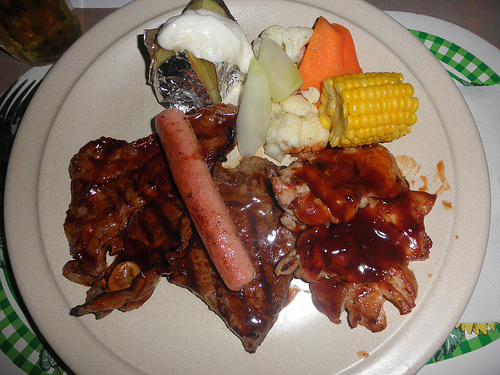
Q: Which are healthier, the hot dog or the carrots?
A: The carrots are healthier than the hot dog.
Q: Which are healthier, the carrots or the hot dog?
A: The carrots are healthier than the hot dog.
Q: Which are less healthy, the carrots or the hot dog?
A: The hot dog are less healthy than the carrots.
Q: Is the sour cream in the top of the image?
A: Yes, the sour cream is in the top of the image.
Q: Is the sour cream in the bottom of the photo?
A: No, the sour cream is in the top of the image.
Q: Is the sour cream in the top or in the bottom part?
A: The sour cream is in the top of the image.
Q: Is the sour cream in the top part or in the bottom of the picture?
A: The sour cream is in the top of the image.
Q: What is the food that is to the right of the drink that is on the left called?
A: The food is sour cream.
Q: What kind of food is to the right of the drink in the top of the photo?
A: The food is sour cream.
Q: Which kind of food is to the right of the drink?
A: The food is sour cream.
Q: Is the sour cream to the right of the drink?
A: Yes, the sour cream is to the right of the drink.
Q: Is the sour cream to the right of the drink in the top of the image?
A: Yes, the sour cream is to the right of the drink.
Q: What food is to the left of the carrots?
A: The food is sour cream.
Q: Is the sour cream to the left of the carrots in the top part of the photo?
A: Yes, the sour cream is to the left of the carrots.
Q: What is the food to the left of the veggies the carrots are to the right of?
A: The food is sour cream.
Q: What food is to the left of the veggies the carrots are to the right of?
A: The food is sour cream.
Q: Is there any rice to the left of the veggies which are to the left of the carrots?
A: No, there is sour cream to the left of the vegetables.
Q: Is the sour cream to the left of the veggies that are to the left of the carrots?
A: Yes, the sour cream is to the left of the vegetables.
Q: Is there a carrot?
A: Yes, there are carrots.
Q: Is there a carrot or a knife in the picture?
A: Yes, there are carrots.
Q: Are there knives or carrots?
A: Yes, there are carrots.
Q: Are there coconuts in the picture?
A: No, there are no coconuts.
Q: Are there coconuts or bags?
A: No, there are no coconuts or bags.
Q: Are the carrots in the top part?
A: Yes, the carrots are in the top of the image.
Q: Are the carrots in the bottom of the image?
A: No, the carrots are in the top of the image.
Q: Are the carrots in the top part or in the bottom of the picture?
A: The carrots are in the top of the image.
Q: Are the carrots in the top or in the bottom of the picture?
A: The carrots are in the top of the image.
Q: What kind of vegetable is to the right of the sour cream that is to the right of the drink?
A: The vegetables are carrots.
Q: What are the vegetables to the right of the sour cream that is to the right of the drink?
A: The vegetables are carrots.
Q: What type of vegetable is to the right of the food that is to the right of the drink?
A: The vegetables are carrots.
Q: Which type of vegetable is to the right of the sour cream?
A: The vegetables are carrots.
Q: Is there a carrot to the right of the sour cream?
A: Yes, there are carrots to the right of the sour cream.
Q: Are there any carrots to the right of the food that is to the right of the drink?
A: Yes, there are carrots to the right of the sour cream.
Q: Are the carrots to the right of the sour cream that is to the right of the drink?
A: Yes, the carrots are to the right of the sour cream.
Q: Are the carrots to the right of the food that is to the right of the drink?
A: Yes, the carrots are to the right of the sour cream.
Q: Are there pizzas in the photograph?
A: No, there are no pizzas.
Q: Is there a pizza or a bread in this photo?
A: No, there are no pizzas or breads.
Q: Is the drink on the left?
A: Yes, the drink is on the left of the image.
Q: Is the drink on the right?
A: No, the drink is on the left of the image.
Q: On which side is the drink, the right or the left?
A: The drink is on the left of the image.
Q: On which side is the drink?
A: The drink is on the left of the image.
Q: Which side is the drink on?
A: The drink is on the left of the image.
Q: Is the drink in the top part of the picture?
A: Yes, the drink is in the top of the image.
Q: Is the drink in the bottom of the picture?
A: No, the drink is in the top of the image.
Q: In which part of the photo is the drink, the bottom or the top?
A: The drink is in the top of the image.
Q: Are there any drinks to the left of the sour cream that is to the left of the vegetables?
A: Yes, there is a drink to the left of the sour cream.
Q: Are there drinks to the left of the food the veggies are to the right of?
A: Yes, there is a drink to the left of the sour cream.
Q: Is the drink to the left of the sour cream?
A: Yes, the drink is to the left of the sour cream.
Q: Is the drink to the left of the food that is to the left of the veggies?
A: Yes, the drink is to the left of the sour cream.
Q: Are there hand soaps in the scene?
A: No, there are no hand soaps.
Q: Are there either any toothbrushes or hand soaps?
A: No, there are no hand soaps or toothbrushes.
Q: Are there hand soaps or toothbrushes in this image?
A: No, there are no hand soaps or toothbrushes.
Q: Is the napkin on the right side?
A: Yes, the napkin is on the right of the image.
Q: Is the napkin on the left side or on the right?
A: The napkin is on the right of the image.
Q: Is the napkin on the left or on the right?
A: The napkin is on the right of the image.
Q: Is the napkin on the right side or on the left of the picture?
A: The napkin is on the right of the image.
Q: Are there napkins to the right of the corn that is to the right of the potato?
A: Yes, there is a napkin to the right of the corn.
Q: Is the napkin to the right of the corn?
A: Yes, the napkin is to the right of the corn.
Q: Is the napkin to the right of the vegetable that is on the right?
A: Yes, the napkin is to the right of the corn.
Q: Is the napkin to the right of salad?
A: No, the napkin is to the right of the corn.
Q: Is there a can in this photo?
A: No, there are no cans.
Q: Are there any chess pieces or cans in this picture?
A: No, there are no cans or chess pieces.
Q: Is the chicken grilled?
A: Yes, the chicken is grilled.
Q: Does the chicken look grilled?
A: Yes, the chicken is grilled.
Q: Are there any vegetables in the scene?
A: Yes, there are vegetables.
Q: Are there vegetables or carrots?
A: Yes, there are vegetables.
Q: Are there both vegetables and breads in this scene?
A: No, there are vegetables but no breads.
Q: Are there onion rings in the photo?
A: No, there are no onion rings.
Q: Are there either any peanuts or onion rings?
A: No, there are no onion rings or peanuts.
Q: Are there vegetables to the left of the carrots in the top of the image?
A: Yes, there are vegetables to the left of the carrots.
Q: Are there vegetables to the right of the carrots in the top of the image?
A: No, the vegetables are to the left of the carrots.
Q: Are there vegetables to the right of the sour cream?
A: Yes, there are vegetables to the right of the sour cream.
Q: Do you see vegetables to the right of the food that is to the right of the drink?
A: Yes, there are vegetables to the right of the sour cream.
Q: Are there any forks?
A: Yes, there is a fork.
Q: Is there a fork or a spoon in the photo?
A: Yes, there is a fork.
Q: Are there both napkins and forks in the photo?
A: Yes, there are both a fork and a napkin.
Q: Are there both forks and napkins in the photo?
A: Yes, there are both a fork and a napkin.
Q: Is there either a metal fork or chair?
A: Yes, there is a metal fork.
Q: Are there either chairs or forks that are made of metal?
A: Yes, the fork is made of metal.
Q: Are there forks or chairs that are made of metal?
A: Yes, the fork is made of metal.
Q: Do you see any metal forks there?
A: Yes, there is a metal fork.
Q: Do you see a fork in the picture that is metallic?
A: Yes, there is a fork that is metallic.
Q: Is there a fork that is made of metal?
A: Yes, there is a fork that is made of metal.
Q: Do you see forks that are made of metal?
A: Yes, there is a fork that is made of metal.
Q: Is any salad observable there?
A: No, there is no salad.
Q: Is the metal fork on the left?
A: Yes, the fork is on the left of the image.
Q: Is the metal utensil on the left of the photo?
A: Yes, the fork is on the left of the image.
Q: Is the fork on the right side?
A: No, the fork is on the left of the image.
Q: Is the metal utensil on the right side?
A: No, the fork is on the left of the image.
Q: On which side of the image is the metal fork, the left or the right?
A: The fork is on the left of the image.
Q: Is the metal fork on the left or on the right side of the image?
A: The fork is on the left of the image.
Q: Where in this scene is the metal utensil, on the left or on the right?
A: The fork is on the left of the image.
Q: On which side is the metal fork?
A: The fork is on the left of the image.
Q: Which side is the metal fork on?
A: The fork is on the left of the image.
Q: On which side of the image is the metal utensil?
A: The fork is on the left of the image.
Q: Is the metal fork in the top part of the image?
A: Yes, the fork is in the top of the image.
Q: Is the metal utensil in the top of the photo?
A: Yes, the fork is in the top of the image.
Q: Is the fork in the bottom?
A: No, the fork is in the top of the image.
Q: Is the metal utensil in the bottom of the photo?
A: No, the fork is in the top of the image.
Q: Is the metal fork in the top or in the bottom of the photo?
A: The fork is in the top of the image.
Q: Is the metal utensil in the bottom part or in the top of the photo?
A: The fork is in the top of the image.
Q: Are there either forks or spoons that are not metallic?
A: No, there is a fork but it is metallic.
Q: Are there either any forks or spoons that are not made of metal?
A: No, there is a fork but it is made of metal.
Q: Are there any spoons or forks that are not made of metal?
A: No, there is a fork but it is made of metal.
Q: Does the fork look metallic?
A: Yes, the fork is metallic.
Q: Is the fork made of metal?
A: Yes, the fork is made of metal.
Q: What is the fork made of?
A: The fork is made of metal.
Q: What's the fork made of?
A: The fork is made of metal.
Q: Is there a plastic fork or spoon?
A: No, there is a fork but it is metallic.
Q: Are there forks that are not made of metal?
A: No, there is a fork but it is made of metal.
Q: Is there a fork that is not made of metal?
A: No, there is a fork but it is made of metal.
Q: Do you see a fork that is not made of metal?
A: No, there is a fork but it is made of metal.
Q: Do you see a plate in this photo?
A: Yes, there is a plate.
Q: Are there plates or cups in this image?
A: Yes, there is a plate.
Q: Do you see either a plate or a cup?
A: Yes, there is a plate.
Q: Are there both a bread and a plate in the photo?
A: No, there is a plate but no breads.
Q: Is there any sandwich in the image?
A: No, there are no sandwiches.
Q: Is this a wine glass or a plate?
A: This is a plate.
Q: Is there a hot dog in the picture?
A: Yes, there is a hot dog.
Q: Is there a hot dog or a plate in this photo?
A: Yes, there is a hot dog.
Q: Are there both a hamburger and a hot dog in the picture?
A: No, there is a hot dog but no hamburgers.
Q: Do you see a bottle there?
A: No, there are no bottles.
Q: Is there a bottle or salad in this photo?
A: No, there are no bottles or salad.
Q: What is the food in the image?
A: The food is a hot dog.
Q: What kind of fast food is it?
A: The food is a hot dog.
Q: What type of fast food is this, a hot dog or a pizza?
A: That is a hot dog.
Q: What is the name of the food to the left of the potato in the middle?
A: The food is a hot dog.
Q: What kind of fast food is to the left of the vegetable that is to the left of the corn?
A: The food is a hot dog.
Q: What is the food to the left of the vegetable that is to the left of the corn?
A: The food is a hot dog.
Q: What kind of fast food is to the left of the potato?
A: The food is a hot dog.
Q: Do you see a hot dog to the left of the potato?
A: Yes, there is a hot dog to the left of the potato.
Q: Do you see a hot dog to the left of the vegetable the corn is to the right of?
A: Yes, there is a hot dog to the left of the potato.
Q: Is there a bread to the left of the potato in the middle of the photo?
A: No, there is a hot dog to the left of the potato.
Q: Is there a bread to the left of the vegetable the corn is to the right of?
A: No, there is a hot dog to the left of the potato.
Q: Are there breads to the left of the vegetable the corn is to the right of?
A: No, there is a hot dog to the left of the potato.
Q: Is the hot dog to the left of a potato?
A: Yes, the hot dog is to the left of a potato.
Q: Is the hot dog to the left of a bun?
A: No, the hot dog is to the left of a potato.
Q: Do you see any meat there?
A: Yes, there is meat.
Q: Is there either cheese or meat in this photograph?
A: Yes, there is meat.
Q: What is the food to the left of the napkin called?
A: The food is meat.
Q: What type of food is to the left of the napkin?
A: The food is meat.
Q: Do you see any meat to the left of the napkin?
A: Yes, there is meat to the left of the napkin.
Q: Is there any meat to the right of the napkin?
A: No, the meat is to the left of the napkin.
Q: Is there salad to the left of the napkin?
A: No, there is meat to the left of the napkin.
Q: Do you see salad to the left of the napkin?
A: No, there is meat to the left of the napkin.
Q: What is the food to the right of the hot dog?
A: The food is meat.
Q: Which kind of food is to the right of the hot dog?
A: The food is meat.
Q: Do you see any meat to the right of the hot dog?
A: Yes, there is meat to the right of the hot dog.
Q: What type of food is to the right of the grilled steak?
A: The food is meat.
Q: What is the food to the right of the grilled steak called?
A: The food is meat.